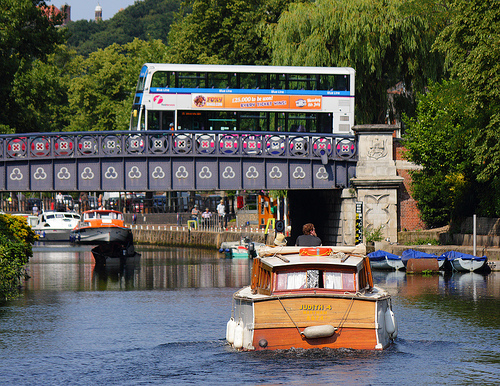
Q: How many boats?
A: Six.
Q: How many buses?
A: One.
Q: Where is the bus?
A: On the bridge.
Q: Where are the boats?
A: River.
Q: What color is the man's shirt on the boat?
A: Blue.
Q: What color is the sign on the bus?
A: Orange.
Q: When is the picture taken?
A: Daytime.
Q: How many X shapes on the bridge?
A: Fifteen.